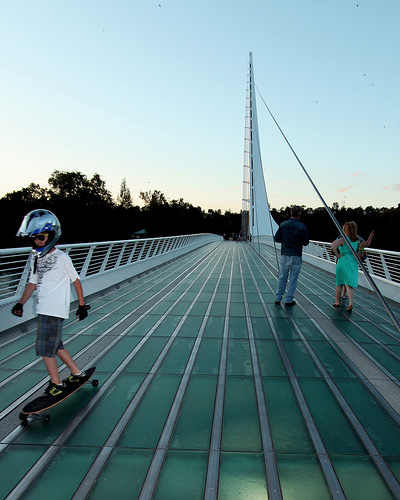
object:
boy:
[11, 201, 91, 400]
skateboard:
[22, 366, 96, 415]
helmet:
[17, 209, 62, 258]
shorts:
[33, 315, 66, 359]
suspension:
[254, 87, 400, 338]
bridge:
[3, 226, 400, 491]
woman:
[328, 219, 367, 317]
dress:
[336, 233, 363, 288]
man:
[273, 206, 317, 311]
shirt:
[273, 218, 310, 258]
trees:
[118, 180, 133, 241]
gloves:
[75, 303, 92, 321]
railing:
[0, 232, 211, 330]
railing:
[249, 227, 400, 311]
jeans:
[274, 256, 302, 302]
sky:
[0, 0, 398, 230]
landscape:
[3, 160, 400, 248]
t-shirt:
[25, 247, 80, 321]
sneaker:
[47, 380, 67, 400]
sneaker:
[69, 370, 85, 386]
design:
[32, 253, 59, 304]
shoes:
[284, 300, 295, 307]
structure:
[240, 51, 274, 239]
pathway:
[2, 229, 400, 491]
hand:
[336, 252, 343, 257]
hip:
[337, 257, 348, 270]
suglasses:
[30, 235, 45, 243]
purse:
[357, 249, 368, 261]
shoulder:
[355, 238, 363, 246]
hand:
[370, 231, 374, 237]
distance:
[3, 7, 400, 249]